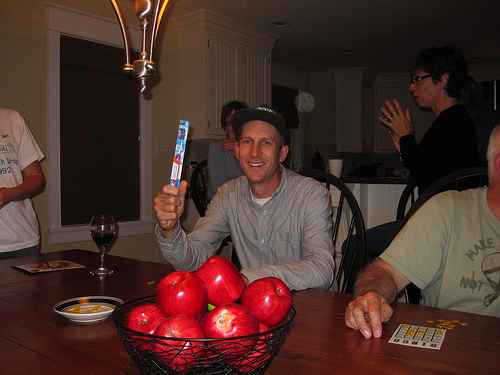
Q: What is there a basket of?
A: Apples.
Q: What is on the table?
A: Bingo card.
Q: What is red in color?
A: Apples.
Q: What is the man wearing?
A: A hat.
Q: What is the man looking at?
A: Camera.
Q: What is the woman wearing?
A: A black shirt.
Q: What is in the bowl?
A: Apples.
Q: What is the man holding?
A: A toothbrush.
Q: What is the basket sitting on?
A: The table.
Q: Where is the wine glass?
A: On the table.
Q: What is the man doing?
A: Holding a toothbrush.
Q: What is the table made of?
A: Wood.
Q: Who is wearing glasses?
A: The woman with brown hair.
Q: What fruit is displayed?
A: Red apples.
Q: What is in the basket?
A: Red apples.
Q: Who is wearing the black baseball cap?
A: The man sitting at the table.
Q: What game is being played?
A: BINGO.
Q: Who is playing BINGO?
A: The people at the table.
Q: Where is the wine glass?
A: On the wooden table.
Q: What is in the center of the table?
A: Apples.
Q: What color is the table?
A: Brown.